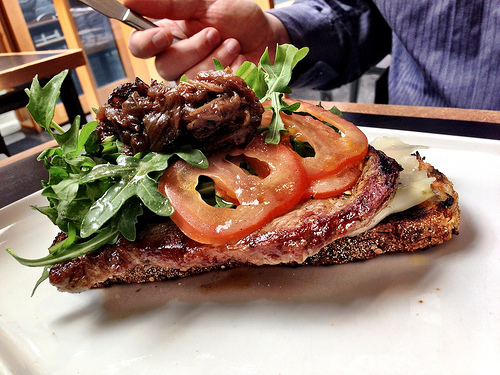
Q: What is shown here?
A: Food.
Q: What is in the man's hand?
A: A knife.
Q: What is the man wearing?
A: A blue shirt.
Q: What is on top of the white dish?
A: Food.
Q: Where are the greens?
A: On top of the food.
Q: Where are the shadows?
A: White plate.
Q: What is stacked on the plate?
A: Food.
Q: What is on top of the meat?
A: Tomato slices.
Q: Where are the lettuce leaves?
A: On the meat.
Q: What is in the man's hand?
A: Knife.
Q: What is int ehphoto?
A: A sandwich.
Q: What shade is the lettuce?
A: Green.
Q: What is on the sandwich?
A: Arugula.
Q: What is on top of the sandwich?
A: Sauteed onions.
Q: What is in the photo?
A: Tomatoes.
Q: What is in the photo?
A: Vegetables.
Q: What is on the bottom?
A: Bread.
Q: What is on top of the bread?
A: Meat.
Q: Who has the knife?
A: A man.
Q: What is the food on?
A: Plate.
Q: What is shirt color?
A: Blue.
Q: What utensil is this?
A: Fork.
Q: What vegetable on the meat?
A: Tomato.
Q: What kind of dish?
A: Meat.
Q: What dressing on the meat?
A: Green.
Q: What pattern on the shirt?
A: Stripes.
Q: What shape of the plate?
A: Square.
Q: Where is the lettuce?
A: Under the onions.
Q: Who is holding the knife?
A: The man.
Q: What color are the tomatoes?
A: Red.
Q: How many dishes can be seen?
A: 1.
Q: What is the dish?
A: Steak and eggs on toast.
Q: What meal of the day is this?
A: Breakfast.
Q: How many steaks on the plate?
A: 1.